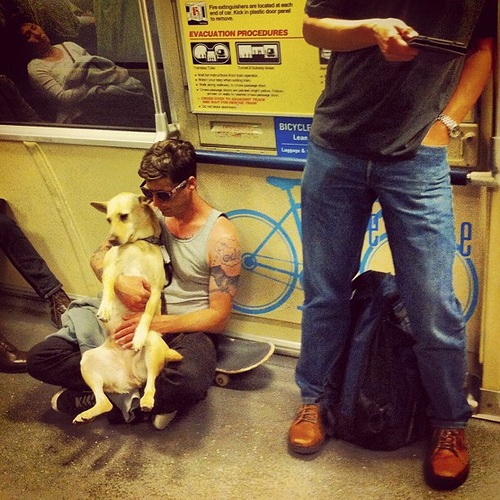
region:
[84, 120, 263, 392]
man sitting with dog on lap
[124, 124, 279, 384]
man sitting on skateboard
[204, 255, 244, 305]
tattoo on man's arm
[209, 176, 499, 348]
blue bicycle on wall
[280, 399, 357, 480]
brown boots on man to the right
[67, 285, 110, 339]
blue coat on man's leg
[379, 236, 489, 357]
blue denim jeans on man's legs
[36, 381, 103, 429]
black and white shoes on man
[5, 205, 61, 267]
skinny jeans on leg to the left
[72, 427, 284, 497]
black solid floor on subway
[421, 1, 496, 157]
man's hand in his pocket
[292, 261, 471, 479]
backpack on ground between man's legs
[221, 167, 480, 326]
blue bicycle image on wall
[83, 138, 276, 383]
man sitting on a skateboard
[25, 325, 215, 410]
man's legs are crossed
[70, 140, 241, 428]
man is holding a dog up next to his body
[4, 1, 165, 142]
reflection in the window of a woman leaning back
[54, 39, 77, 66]
dark strap across woman's shoulder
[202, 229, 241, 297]
tattoos on man's upper arm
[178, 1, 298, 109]
instructions on a yellow board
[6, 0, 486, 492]
Scene inside a subway train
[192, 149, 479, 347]
Painting of turquoise bicycle on train wall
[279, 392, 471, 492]
Pair of reddish brown laced shoes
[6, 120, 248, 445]
Man sitting on floor holding a white dog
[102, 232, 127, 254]
Dog's dark brown nose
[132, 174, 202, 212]
Pair of plastic dark sunglasses on man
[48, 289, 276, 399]
Black skateboard being used as a seat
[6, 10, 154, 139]
Reflection of woman sleeping in seat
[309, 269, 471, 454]
Navy blue back pack on floor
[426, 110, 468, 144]
Men's silver wristwatch with dark clock face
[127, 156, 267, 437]
the guy has glasses on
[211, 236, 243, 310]
tattois on the arm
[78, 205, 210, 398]
the dog is white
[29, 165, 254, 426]
the man is wearing a vest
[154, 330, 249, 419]
the pants are black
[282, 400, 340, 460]
the shos are brown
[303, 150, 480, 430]
the jeans are blue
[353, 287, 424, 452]
the bag is black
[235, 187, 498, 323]
the bike is blue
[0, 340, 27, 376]
th shoes are dark brown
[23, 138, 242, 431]
young man holding a dog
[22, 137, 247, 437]
young man sitting on a skateboard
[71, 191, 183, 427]
dog being held by a young man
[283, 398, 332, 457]
man's brown right shoe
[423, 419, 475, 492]
man's brown left shoe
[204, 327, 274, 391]
skateboard under man and dog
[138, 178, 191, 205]
sunglasses worn by young man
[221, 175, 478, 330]
picture of bicycle drawn on wall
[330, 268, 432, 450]
man's backpack on ground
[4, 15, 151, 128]
woman in white shirt